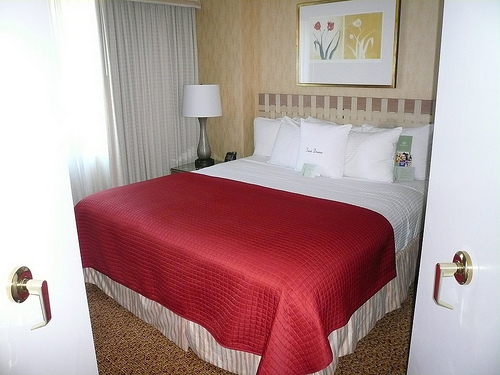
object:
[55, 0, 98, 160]
window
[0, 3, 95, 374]
door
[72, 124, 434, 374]
bed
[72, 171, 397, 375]
quilt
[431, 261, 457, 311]
handle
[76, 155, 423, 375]
sheet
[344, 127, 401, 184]
pillows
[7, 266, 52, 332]
handle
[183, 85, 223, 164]
lamp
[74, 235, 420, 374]
bedskirt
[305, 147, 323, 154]
words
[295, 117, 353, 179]
pillow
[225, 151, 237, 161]
clock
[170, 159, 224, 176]
table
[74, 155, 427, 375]
bed spread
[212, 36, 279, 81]
wall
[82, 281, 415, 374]
carpet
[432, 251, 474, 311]
gold handle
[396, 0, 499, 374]
door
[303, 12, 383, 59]
flowers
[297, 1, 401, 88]
picture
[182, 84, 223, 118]
shade